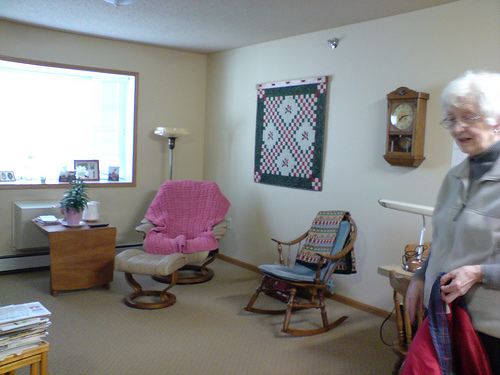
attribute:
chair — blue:
[243, 203, 366, 339]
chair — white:
[108, 159, 234, 333]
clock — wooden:
[390, 101, 417, 130]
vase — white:
[64, 205, 84, 225]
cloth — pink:
[157, 179, 219, 232]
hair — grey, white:
[439, 72, 499, 97]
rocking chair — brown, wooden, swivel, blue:
[237, 208, 366, 341]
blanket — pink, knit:
[167, 192, 207, 228]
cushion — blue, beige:
[283, 269, 299, 277]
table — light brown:
[46, 226, 115, 265]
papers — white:
[2, 298, 57, 356]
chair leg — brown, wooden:
[280, 301, 334, 337]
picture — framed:
[71, 156, 103, 184]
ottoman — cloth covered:
[110, 245, 196, 316]